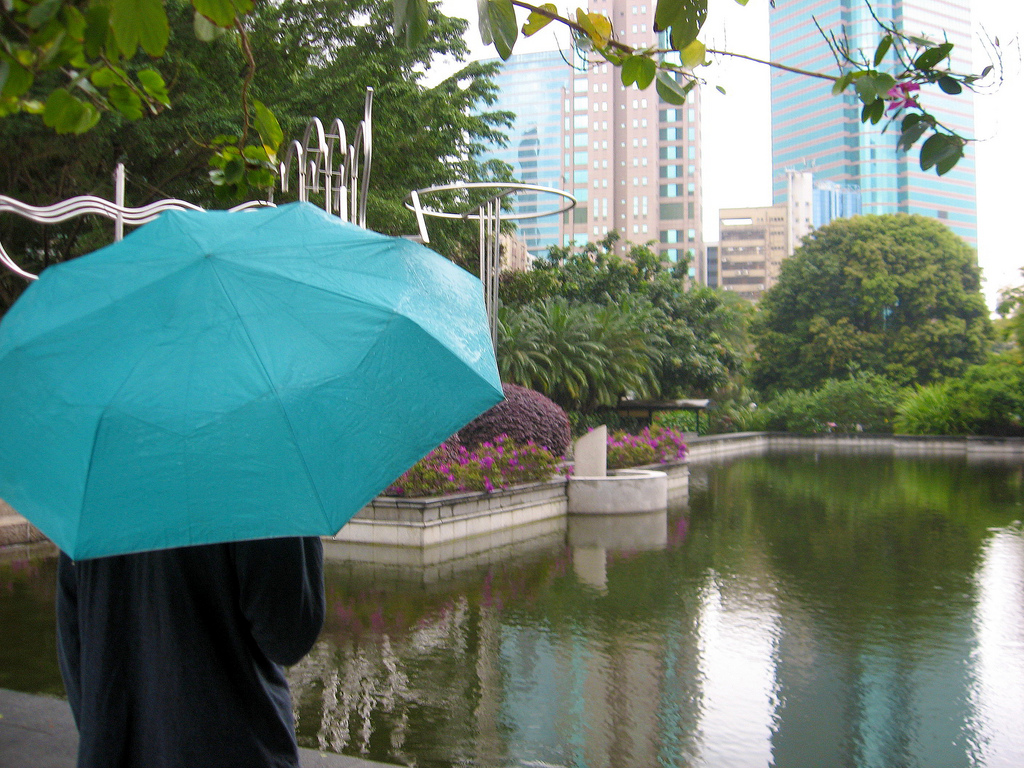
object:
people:
[53, 500, 328, 768]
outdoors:
[0, 0, 1024, 768]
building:
[469, 50, 570, 270]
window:
[659, 165, 683, 178]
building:
[768, 0, 979, 236]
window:
[573, 169, 587, 183]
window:
[643, 118, 648, 127]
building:
[586, 0, 695, 336]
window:
[659, 126, 683, 140]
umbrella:
[0, 200, 509, 566]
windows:
[722, 276, 764, 285]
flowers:
[458, 382, 571, 456]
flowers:
[607, 423, 690, 468]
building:
[561, 87, 569, 265]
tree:
[0, 0, 517, 314]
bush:
[498, 211, 999, 409]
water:
[0, 453, 1022, 765]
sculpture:
[0, 163, 277, 281]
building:
[718, 206, 787, 305]